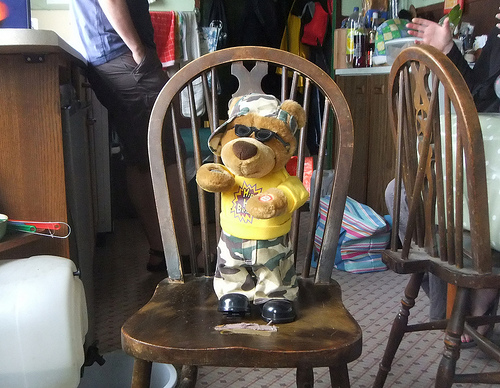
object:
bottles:
[338, 8, 393, 63]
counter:
[333, 63, 415, 87]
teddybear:
[198, 92, 310, 318]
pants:
[213, 235, 304, 319]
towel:
[145, 12, 176, 69]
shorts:
[82, 44, 189, 172]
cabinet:
[351, 68, 390, 222]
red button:
[256, 193, 274, 204]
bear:
[189, 86, 316, 325]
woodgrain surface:
[2, 53, 70, 253]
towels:
[174, 9, 198, 113]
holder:
[191, 7, 198, 16]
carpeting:
[346, 274, 392, 316]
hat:
[204, 94, 308, 156]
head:
[209, 102, 302, 180]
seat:
[101, 188, 391, 372]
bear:
[194, 91, 311, 326]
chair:
[380, 35, 497, 385]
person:
[442, 17, 498, 126]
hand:
[405, 17, 454, 57]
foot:
[376, 282, 494, 388]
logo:
[231, 179, 252, 220]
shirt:
[214, 167, 308, 239]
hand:
[242, 192, 276, 219]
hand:
[195, 160, 231, 193]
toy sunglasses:
[216, 109, 333, 144]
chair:
[121, 40, 368, 387]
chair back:
[151, 55, 339, 282]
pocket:
[127, 61, 166, 99]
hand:
[131, 47, 145, 63]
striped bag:
[331, 188, 394, 269]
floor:
[314, 263, 486, 385]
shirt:
[74, 0, 149, 68]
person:
[61, 1, 209, 273]